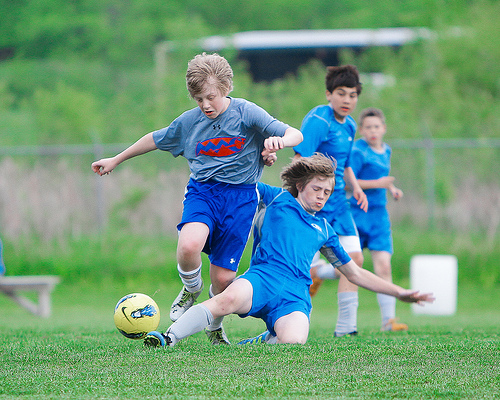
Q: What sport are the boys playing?
A: Soccer.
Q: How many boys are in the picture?
A: Four.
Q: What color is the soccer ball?
A: Yellow.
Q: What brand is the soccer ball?
A: Nike.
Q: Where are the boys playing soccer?
A: Soccer field.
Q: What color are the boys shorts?
A: Blue.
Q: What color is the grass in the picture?
A: Green.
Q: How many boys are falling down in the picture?
A: One.